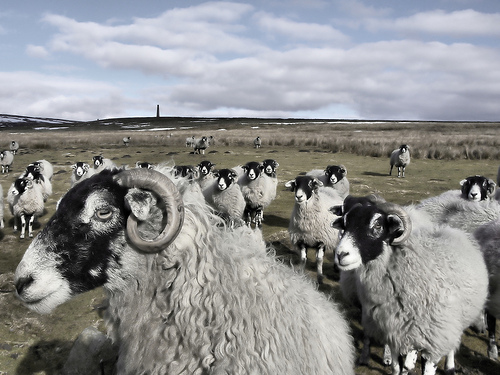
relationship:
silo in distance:
[156, 102, 163, 116] [0, 61, 500, 151]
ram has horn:
[12, 160, 491, 375] [113, 162, 185, 252]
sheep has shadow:
[7, 171, 49, 244] [13, 212, 41, 234]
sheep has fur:
[0, 126, 498, 374] [411, 251, 468, 304]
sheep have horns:
[0, 126, 498, 374] [21, 154, 499, 277]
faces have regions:
[12, 175, 398, 300] [15, 176, 388, 315]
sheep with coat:
[379, 141, 421, 182] [386, 142, 415, 182]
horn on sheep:
[113, 162, 185, 252] [13, 165, 356, 374]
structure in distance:
[148, 98, 169, 118] [0, 61, 500, 151]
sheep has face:
[7, 171, 49, 244] [10, 175, 27, 199]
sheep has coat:
[7, 171, 49, 244] [4, 173, 60, 245]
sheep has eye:
[13, 165, 356, 374] [88, 200, 121, 230]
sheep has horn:
[13, 165, 356, 374] [113, 162, 185, 252]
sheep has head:
[13, 165, 356, 374] [4, 150, 219, 325]